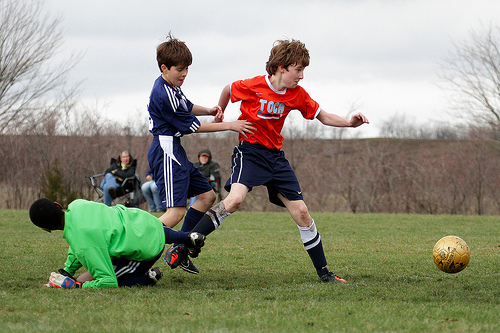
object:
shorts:
[233, 147, 303, 211]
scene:
[10, 5, 482, 330]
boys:
[33, 196, 207, 293]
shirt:
[25, 183, 176, 293]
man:
[102, 151, 140, 207]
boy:
[194, 36, 368, 286]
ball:
[430, 234, 471, 273]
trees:
[0, 0, 130, 205]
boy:
[145, 38, 257, 291]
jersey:
[223, 77, 329, 164]